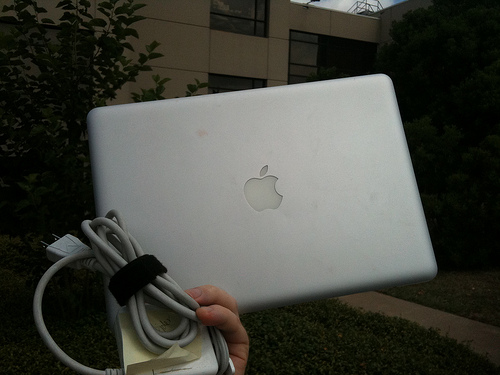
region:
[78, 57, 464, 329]
A white laptop computer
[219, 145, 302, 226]
Laptop has a apple logo on it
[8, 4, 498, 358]
Photo was taken in the daytime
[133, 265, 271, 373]
A hand is holding the laptop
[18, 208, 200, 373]
A white electronic plug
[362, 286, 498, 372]
A concrete sidewalk in the background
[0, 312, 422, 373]
Grass is covering the ground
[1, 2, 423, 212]
A building is in the background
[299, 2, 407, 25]
The sky is cloudy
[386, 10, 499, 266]
A large green bush is in the background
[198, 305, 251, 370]
a finger that is grasping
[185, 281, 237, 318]
a finger that is grasping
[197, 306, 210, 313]
a fingernail on a finger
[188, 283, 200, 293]
a fingernail on a finger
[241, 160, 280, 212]
the apple logo on an apple computer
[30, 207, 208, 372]
a wrapped up gray cord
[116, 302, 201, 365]
a yellow post it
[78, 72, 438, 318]
a grey metal laptop computer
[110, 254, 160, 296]
the black velcro strap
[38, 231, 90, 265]
the grey plug of a cord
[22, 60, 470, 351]
laptop and cord in front of building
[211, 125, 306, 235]
company logo of bitten apple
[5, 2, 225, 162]
bush with branches pointing upwards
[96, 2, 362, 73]
tan building with dark windows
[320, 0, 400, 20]
airy structure on top of building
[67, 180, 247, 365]
fingers curved over bundled wires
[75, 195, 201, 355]
black strap in middle of loops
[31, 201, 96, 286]
prong in back of curved cord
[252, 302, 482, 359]
grass growing next to ledge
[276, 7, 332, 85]
window panes in a column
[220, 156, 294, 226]
company logo on a laptop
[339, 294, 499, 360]
sidewalk between grass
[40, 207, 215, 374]
gray computer power cord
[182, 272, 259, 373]
a persons hand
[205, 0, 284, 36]
windows of a building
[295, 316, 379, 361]
patch of wild grass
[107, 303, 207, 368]
sticky note on a computer charger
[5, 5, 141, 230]
green bush in front of a building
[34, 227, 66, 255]
metal prongs for electrical outlet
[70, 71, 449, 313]
white laptop computer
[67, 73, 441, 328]
silver Apple Mac laptop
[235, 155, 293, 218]
tiny silver apple logo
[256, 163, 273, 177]
tiny silver leaf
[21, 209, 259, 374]
silver cords that have been wrapped up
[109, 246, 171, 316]
thick black strap holding together the cord bundle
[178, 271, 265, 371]
two fingers wrapped around the cords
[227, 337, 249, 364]
wrikles in the skin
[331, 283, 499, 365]
concrete sidewalk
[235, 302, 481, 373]
patch of dark green grass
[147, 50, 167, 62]
green leaf